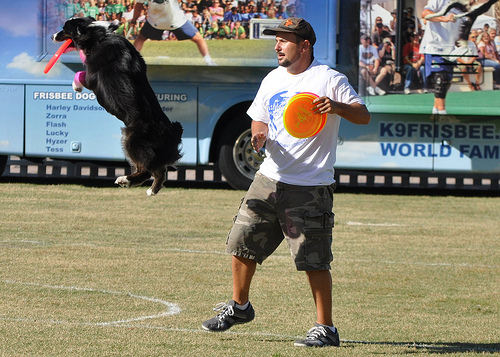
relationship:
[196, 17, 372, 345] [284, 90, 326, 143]
man holds frisbee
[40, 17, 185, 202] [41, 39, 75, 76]
dog holds frisbee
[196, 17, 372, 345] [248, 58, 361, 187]
man wears shirt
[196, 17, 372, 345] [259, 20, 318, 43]
man wears cap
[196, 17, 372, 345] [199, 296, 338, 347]
man wears shoes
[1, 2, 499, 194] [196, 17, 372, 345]
bus behind man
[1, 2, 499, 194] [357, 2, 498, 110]
bus has picture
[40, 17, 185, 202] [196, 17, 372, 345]
dog with man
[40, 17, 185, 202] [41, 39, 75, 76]
dog catches frisbee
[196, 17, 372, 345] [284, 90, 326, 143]
man plays frisbee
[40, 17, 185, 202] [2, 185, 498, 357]
dog on playground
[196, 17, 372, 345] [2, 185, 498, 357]
man on playground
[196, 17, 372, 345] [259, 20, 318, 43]
man wears hat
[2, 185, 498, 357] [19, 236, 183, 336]
playground has lines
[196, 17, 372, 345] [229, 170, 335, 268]
man wears shorts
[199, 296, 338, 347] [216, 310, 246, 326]
shoes have stripes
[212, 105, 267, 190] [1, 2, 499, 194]
wheel on bus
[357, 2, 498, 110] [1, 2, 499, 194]
picture on bus